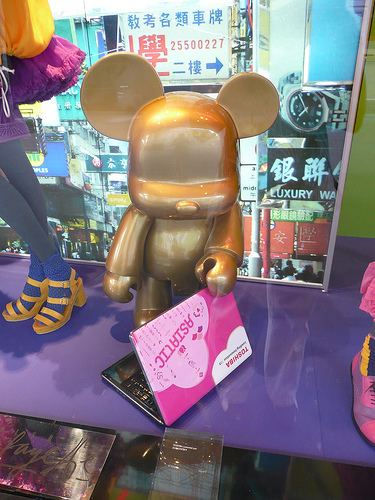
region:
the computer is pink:
[154, 316, 256, 394]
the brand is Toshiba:
[226, 349, 249, 365]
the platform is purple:
[247, 289, 348, 458]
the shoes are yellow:
[44, 275, 94, 324]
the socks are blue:
[42, 252, 73, 320]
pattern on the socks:
[46, 261, 71, 282]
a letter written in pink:
[150, 356, 166, 372]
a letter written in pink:
[160, 348, 167, 362]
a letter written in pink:
[163, 345, 176, 358]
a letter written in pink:
[170, 338, 183, 351]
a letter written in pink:
[170, 325, 200, 356]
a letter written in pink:
[178, 323, 199, 338]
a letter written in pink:
[180, 322, 190, 334]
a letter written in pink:
[182, 313, 197, 325]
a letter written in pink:
[220, 358, 227, 369]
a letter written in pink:
[229, 358, 233, 363]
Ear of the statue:
[73, 50, 166, 153]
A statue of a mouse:
[77, 43, 280, 303]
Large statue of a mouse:
[78, 38, 285, 288]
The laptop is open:
[93, 295, 265, 426]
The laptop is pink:
[89, 302, 253, 427]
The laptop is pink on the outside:
[95, 307, 255, 430]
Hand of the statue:
[190, 246, 243, 299]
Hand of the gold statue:
[190, 250, 247, 301]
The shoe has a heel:
[30, 270, 90, 334]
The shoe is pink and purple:
[341, 345, 373, 438]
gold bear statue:
[78, 52, 280, 337]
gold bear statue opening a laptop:
[76, 48, 280, 427]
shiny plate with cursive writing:
[0, 411, 117, 498]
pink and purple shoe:
[348, 348, 373, 449]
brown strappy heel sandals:
[3, 269, 88, 337]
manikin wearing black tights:
[1, 0, 86, 336]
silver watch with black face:
[275, 68, 351, 133]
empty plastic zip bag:
[140, 427, 226, 498]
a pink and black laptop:
[101, 285, 252, 425]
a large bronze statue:
[80, 51, 280, 327]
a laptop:
[114, 310, 250, 406]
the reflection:
[264, 309, 317, 396]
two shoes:
[0, 276, 84, 331]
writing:
[267, 154, 328, 184]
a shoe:
[350, 344, 373, 436]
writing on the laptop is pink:
[147, 312, 195, 368]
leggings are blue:
[7, 191, 49, 245]